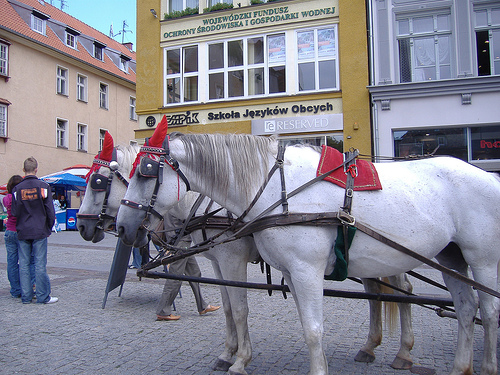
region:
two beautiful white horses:
[80, 115, 498, 373]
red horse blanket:
[282, 133, 427, 205]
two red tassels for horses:
[63, 115, 178, 188]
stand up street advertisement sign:
[91, 232, 140, 317]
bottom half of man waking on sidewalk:
[129, 227, 227, 354]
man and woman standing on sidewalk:
[6, 152, 63, 308]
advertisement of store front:
[114, 85, 356, 148]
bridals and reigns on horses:
[73, 135, 405, 265]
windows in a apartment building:
[8, 8, 130, 153]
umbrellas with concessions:
[36, 157, 97, 235]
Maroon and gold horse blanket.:
[293, 148, 393, 197]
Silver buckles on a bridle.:
[335, 128, 365, 226]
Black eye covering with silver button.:
[130, 150, 167, 176]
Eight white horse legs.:
[167, 327, 494, 367]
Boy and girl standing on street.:
[5, 143, 75, 323]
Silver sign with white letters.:
[276, 115, 343, 137]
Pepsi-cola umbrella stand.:
[45, 150, 85, 231]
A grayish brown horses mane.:
[160, 125, 283, 228]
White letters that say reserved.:
[275, 115, 332, 132]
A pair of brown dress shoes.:
[99, 290, 224, 321]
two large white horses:
[83, 108, 473, 371]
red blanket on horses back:
[314, 133, 378, 197]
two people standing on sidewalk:
[5, 151, 66, 311]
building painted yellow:
[136, 0, 365, 152]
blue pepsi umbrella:
[42, 150, 89, 232]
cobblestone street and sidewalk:
[43, 245, 105, 353]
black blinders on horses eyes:
[79, 154, 166, 201]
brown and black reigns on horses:
[81, 157, 301, 245]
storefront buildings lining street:
[144, 5, 496, 150]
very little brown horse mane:
[190, 128, 278, 200]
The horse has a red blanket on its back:
[302, 142, 389, 233]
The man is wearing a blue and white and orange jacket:
[19, 179, 53, 234]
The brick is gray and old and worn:
[75, 335, 84, 372]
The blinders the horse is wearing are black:
[136, 160, 162, 191]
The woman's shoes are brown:
[161, 295, 222, 321]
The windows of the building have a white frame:
[47, 69, 104, 115]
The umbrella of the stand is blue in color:
[44, 170, 86, 205]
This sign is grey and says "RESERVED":
[256, 113, 337, 134]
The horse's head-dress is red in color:
[139, 112, 175, 157]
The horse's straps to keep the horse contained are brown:
[320, 207, 387, 282]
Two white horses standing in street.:
[73, 128, 495, 373]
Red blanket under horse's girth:
[311, 140, 393, 197]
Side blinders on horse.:
[136, 152, 173, 190]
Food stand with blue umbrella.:
[47, 163, 92, 240]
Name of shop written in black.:
[201, 98, 343, 127]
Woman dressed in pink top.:
[3, 193, 17, 233]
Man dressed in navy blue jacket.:
[11, 172, 66, 247]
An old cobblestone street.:
[62, 311, 155, 366]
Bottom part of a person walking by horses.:
[146, 251, 231, 329]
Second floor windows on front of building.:
[151, 36, 348, 107]